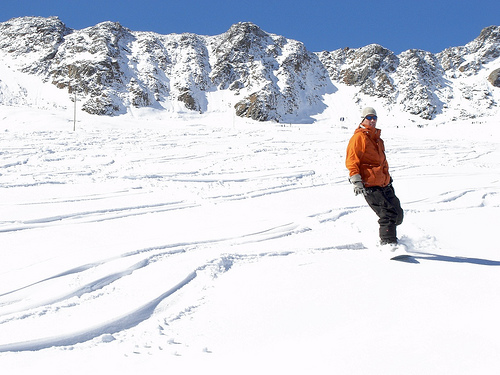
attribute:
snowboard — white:
[382, 238, 414, 258]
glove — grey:
[349, 174, 364, 196]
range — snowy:
[1, 16, 498, 130]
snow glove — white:
[353, 172, 368, 198]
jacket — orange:
[344, 124, 402, 186]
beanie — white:
[367, 106, 379, 125]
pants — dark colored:
[364, 185, 405, 242]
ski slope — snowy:
[0, 120, 498, 374]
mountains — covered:
[5, 3, 499, 118]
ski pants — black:
[363, 182, 423, 227]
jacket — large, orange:
[345, 125, 391, 186]